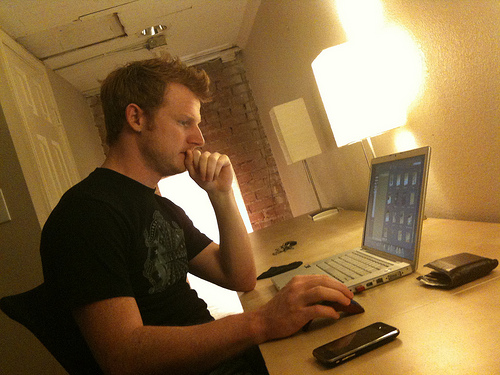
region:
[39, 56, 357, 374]
Man sitting in a chair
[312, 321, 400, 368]
Black cell phone on table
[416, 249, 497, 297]
Black wallet sitting on table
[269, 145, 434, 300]
Silver laptop computer on table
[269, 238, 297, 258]
Car keys laying on table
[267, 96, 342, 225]
Table lamp turned off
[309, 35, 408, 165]
Table lamp turned on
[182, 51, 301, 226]
Brick wall in background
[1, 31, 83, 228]
White door on wall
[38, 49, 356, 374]
Man wearing a black t-shirt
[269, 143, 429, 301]
Open white laptop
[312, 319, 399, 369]
Black smartphone on a desk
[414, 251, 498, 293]
Closed black leather wallet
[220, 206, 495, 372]
Light brown wood desk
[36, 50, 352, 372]
Man using a laptop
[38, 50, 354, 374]
Man wearing a black shirt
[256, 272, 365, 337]
Hand on a curved mouse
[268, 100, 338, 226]
White shade desk lamp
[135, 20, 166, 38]
Circular metal ceiling light fixture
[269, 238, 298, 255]
Set of keys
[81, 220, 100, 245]
the shirt is black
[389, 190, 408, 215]
the computer is on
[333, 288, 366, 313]
his hand is on the mouse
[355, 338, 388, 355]
the phone is on the table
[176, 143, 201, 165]
his hand is up to his mouth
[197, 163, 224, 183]
his fingers are folded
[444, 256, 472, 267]
the wallet is black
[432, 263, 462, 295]
the wallet is on the table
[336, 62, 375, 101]
the light is on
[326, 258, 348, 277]
the laptop is gray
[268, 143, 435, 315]
a lap top is open on the counter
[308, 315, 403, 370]
a cell phone is on the counter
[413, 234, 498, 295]
a wallet is on the counter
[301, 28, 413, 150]
the lamp is turned on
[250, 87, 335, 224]
this lamp is turned off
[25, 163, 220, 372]
the man wears a black t-shirt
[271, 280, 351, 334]
the man uses a mouse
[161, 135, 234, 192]
the man touches his hand to his mouth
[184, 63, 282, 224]
a red brick wall is in the background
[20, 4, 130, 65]
a ceiling tile has lifted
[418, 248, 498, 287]
a man's black wallet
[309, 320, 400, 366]
a black smartphone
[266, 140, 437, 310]
a gray laptop computer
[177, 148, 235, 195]
the hand of a man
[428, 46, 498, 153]
part of a white wall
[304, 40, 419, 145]
a bright lamp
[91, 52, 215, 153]
a man's orange hair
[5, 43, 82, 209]
part of a white door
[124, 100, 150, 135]
the ear of a man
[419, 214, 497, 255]
part of a brown computer desk